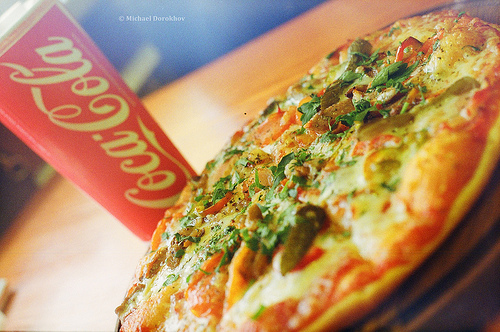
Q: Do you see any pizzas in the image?
A: Yes, there is a pizza.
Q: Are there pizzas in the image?
A: Yes, there is a pizza.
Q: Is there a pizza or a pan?
A: Yes, there is a pizza.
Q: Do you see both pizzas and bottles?
A: No, there is a pizza but no bottles.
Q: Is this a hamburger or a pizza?
A: This is a pizza.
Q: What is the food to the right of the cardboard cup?
A: The food is a pizza.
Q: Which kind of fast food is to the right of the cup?
A: The food is a pizza.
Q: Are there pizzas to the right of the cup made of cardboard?
A: Yes, there is a pizza to the right of the cup.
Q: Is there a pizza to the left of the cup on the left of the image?
A: No, the pizza is to the right of the cup.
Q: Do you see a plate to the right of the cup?
A: No, there is a pizza to the right of the cup.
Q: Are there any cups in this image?
A: Yes, there is a cup.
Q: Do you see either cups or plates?
A: Yes, there is a cup.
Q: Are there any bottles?
A: No, there are no bottles.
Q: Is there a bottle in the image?
A: No, there are no bottles.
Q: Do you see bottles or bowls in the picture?
A: No, there are no bottles or bowls.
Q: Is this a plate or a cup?
A: This is a cup.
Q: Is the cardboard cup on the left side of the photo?
A: Yes, the cup is on the left of the image.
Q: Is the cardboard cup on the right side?
A: No, the cup is on the left of the image.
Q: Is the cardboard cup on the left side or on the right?
A: The cup is on the left of the image.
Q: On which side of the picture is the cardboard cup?
A: The cup is on the left of the image.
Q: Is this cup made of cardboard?
A: Yes, the cup is made of cardboard.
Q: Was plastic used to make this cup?
A: No, the cup is made of cardboard.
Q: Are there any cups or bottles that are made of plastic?
A: No, there is a cup but it is made of cardboard.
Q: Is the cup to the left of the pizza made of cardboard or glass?
A: The cup is made of cardboard.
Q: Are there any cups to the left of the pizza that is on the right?
A: Yes, there is a cup to the left of the pizza.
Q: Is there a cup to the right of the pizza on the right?
A: No, the cup is to the left of the pizza.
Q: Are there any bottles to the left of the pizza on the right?
A: No, there is a cup to the left of the pizza.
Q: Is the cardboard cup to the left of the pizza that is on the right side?
A: Yes, the cup is to the left of the pizza.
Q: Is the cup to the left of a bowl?
A: No, the cup is to the left of the pizza.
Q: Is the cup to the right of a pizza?
A: No, the cup is to the left of a pizza.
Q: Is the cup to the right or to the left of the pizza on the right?
A: The cup is to the left of the pizza.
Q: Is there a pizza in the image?
A: Yes, there is a pizza.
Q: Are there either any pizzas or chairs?
A: Yes, there is a pizza.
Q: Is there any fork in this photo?
A: No, there are no forks.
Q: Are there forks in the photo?
A: No, there are no forks.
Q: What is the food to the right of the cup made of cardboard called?
A: The food is a pizza.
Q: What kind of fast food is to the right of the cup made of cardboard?
A: The food is a pizza.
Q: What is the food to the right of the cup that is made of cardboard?
A: The food is a pizza.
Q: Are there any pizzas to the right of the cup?
A: Yes, there is a pizza to the right of the cup.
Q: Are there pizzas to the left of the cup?
A: No, the pizza is to the right of the cup.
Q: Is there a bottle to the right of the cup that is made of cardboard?
A: No, there is a pizza to the right of the cup.